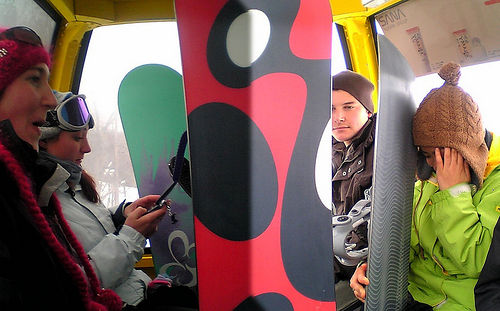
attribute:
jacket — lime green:
[388, 156, 498, 309]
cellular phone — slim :
[148, 181, 181, 208]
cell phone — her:
[137, 181, 179, 217]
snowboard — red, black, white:
[176, 0, 336, 309]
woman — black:
[1, 19, 118, 308]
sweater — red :
[3, 147, 128, 306]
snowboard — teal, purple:
[116, 63, 196, 292]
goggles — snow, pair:
[42, 92, 104, 141]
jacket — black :
[328, 120, 378, 267]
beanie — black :
[302, 60, 390, 110]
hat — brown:
[413, 62, 488, 188]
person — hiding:
[352, 63, 497, 309]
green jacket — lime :
[407, 171, 499, 301]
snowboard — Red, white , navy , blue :
[166, 0, 348, 309]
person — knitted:
[385, 87, 497, 307]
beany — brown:
[409, 57, 490, 182]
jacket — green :
[407, 162, 499, 309]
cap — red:
[0, 22, 51, 69]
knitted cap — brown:
[330, 68, 376, 117]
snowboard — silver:
[362, 27, 415, 307]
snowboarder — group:
[352, 78, 499, 309]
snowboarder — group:
[332, 70, 377, 277]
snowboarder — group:
[0, 27, 121, 309]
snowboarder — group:
[40, 87, 167, 308]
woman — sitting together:
[0, 22, 202, 309]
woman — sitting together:
[36, 82, 196, 309]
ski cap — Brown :
[407, 58, 484, 190]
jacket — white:
[58, 181, 188, 290]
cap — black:
[327, 62, 371, 118]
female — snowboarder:
[0, 21, 96, 306]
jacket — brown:
[326, 112, 375, 249]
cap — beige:
[409, 60, 490, 189]